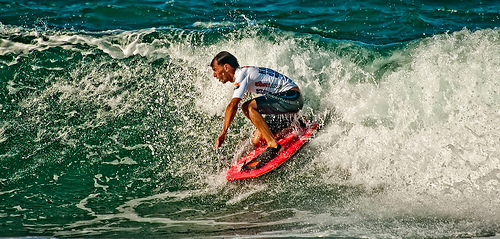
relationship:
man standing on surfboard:
[207, 49, 324, 165] [227, 110, 332, 179]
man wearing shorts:
[207, 49, 324, 165] [256, 88, 305, 115]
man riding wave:
[207, 49, 324, 165] [1, 25, 499, 226]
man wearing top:
[207, 49, 324, 165] [227, 66, 298, 107]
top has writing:
[227, 66, 298, 107] [252, 66, 286, 99]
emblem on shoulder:
[233, 79, 241, 91] [231, 67, 248, 89]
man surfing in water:
[207, 49, 324, 165] [2, 4, 497, 237]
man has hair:
[207, 49, 324, 165] [208, 51, 238, 70]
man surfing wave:
[207, 49, 324, 165] [1, 25, 499, 226]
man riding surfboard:
[207, 49, 324, 165] [227, 110, 332, 179]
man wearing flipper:
[207, 49, 324, 165] [239, 143, 285, 171]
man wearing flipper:
[207, 49, 324, 165] [261, 113, 307, 132]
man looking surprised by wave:
[207, 49, 324, 165] [1, 25, 499, 226]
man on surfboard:
[207, 49, 324, 165] [227, 110, 332, 179]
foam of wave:
[195, 30, 490, 213] [1, 25, 499, 226]